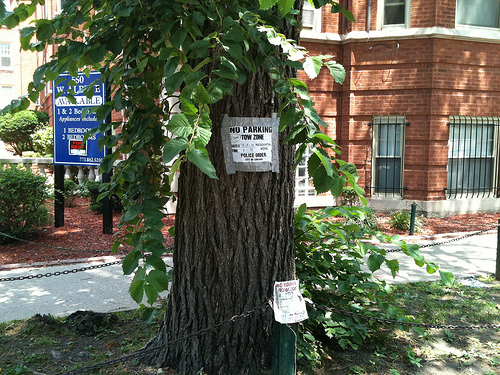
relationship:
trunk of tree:
[171, 48, 292, 342] [78, 6, 309, 374]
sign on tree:
[212, 111, 290, 180] [78, 6, 309, 374]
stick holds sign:
[45, 164, 118, 236] [49, 71, 110, 170]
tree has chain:
[78, 6, 309, 374] [95, 295, 270, 352]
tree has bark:
[78, 6, 309, 374] [247, 80, 273, 110]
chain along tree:
[95, 295, 270, 352] [78, 6, 309, 374]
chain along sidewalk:
[3, 256, 116, 287] [5, 261, 149, 309]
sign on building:
[67, 138, 90, 157] [343, 2, 496, 212]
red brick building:
[390, 69, 432, 90] [343, 2, 496, 212]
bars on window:
[366, 112, 409, 203] [362, 113, 498, 201]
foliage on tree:
[115, 6, 210, 167] [78, 6, 309, 374]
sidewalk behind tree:
[5, 261, 149, 309] [78, 6, 309, 374]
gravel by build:
[409, 216, 494, 240] [343, 2, 496, 212]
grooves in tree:
[177, 187, 269, 299] [78, 6, 309, 374]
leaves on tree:
[107, 21, 169, 226] [78, 6, 309, 374]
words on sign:
[69, 140, 87, 151] [67, 138, 90, 157]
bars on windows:
[366, 112, 409, 203] [362, 113, 498, 201]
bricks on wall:
[378, 62, 442, 96] [353, 52, 435, 113]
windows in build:
[363, 109, 499, 160] [343, 2, 496, 212]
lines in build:
[306, 15, 457, 51] [343, 2, 496, 212]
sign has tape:
[212, 111, 290, 180] [218, 110, 283, 132]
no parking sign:
[227, 125, 276, 165] [212, 111, 290, 180]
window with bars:
[362, 113, 498, 201] [366, 112, 409, 203]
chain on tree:
[95, 295, 270, 352] [78, 6, 309, 374]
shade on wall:
[366, 51, 474, 109] [353, 52, 435, 113]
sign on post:
[49, 71, 110, 170] [45, 164, 118, 236]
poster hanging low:
[271, 277, 316, 327] [263, 265, 325, 375]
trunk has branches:
[171, 48, 292, 342] [111, 11, 210, 295]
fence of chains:
[8, 262, 191, 366] [12, 255, 139, 280]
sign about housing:
[49, 71, 110, 170] [51, 62, 118, 235]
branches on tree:
[111, 11, 210, 295] [78, 6, 309, 374]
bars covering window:
[366, 112, 409, 203] [362, 113, 498, 201]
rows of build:
[347, 45, 496, 116] [343, 2, 496, 212]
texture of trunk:
[194, 195, 292, 274] [171, 48, 292, 342]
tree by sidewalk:
[78, 6, 309, 374] [5, 261, 149, 309]